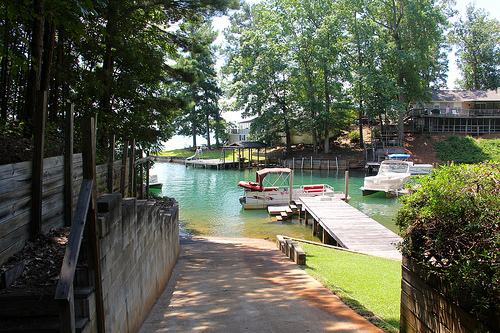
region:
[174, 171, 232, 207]
Beautiful blue lake water near the boat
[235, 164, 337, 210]
A boat sitting in the water by the dock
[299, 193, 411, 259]
A wooden dock by the boat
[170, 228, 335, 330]
Long black shadows on the ground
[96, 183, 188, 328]
A stone wall next to the dirt path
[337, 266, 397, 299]
Short green grass grows on the ground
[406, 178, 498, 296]
A short green hedge by the dirt path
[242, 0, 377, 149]
Tall green trees in the distance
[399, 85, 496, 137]
A wooden building by the tall trees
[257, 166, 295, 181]
A small canopy on the boat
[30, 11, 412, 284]
this is a dock area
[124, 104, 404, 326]
this is a river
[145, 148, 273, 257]
the river water is blue and brown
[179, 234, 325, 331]
this path goes to the river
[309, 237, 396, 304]
there is a lawn along the river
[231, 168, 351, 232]
this boat is docked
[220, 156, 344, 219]
the boat is brown and red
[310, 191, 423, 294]
the dock is made of wood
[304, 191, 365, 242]
the dock is light brown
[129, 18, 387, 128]
these trees are very tall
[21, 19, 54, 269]
This is a tree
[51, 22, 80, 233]
This is a tree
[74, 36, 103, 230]
This is a tree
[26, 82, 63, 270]
This is a pole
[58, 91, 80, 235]
This is a pole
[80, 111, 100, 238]
This is a pole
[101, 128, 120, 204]
This is a pole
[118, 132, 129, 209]
This is a pole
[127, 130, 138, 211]
This is a pole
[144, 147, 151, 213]
This is a pole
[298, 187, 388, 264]
a small and brown pier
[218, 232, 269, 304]
the shade of a tree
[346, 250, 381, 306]
a patch of green grass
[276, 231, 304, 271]
small stones on the side of the road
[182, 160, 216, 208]
a big blue clear lake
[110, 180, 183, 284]
a wall made out of stone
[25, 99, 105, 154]
small brown wooden posts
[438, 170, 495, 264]
a bush made of small leaves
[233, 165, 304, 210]
a small white boat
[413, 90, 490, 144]
a large house with many windows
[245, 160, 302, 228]
boat at the dock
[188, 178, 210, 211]
the water is green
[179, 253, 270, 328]
the path is shaded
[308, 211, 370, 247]
the dock is wood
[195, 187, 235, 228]
the body of water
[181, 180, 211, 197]
the water is calm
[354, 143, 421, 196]
the boat is on the water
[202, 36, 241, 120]
clouds through the trees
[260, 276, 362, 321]
dark spots on sand